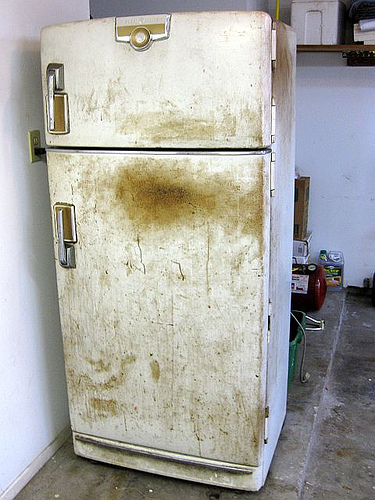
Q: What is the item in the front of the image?
A: Refrigerator.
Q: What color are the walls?
A: White.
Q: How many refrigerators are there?
A: One.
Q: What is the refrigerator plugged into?
A: Wall outlet.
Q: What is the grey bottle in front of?
A: The wall.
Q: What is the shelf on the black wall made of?
A: Wood.